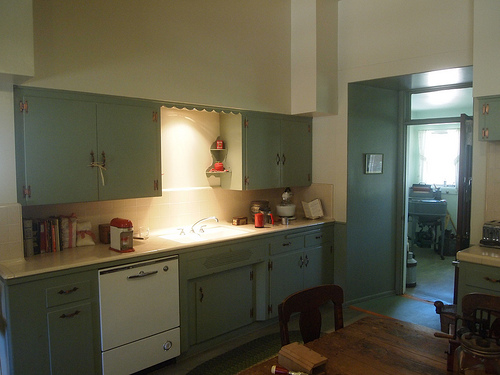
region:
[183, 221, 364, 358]
GREEN CABINETS IN KITCHEN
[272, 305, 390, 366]
WOOD FLOOR OF KITCHEN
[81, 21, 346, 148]
WHITE WALL IN KITCHEN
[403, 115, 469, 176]
WINDOW IN OTHER ROOM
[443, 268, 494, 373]
SMALL CHAIRS IN KITCHEN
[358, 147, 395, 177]
WHITE PHOTO ON WALL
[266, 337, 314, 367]
SMALL BOOOK ON TABLE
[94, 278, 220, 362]
WHITE DISHWASHER IN KITCHEN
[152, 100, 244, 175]
LIGHT OVER SINK IN KITCHEN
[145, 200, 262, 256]
WHITE KITCHEN SINK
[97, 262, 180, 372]
The white dishwasher.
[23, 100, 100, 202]
A green kitchen cabnet.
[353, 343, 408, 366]
Part of the wood table.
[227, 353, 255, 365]
Part of the blue rug.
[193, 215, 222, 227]
The silver water faucet.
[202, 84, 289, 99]
Part of the white wall.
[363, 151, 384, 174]
A picture on the wall.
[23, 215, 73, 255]
Books on the counter.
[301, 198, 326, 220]
An open book on the counter.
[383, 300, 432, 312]
Part of the floor.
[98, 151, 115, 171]
handle on cabinet door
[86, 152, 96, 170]
handle on cabinet door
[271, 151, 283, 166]
handle on cabinet door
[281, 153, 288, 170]
handle on cabinet door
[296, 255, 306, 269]
handle on cabinet door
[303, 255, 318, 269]
handle on cabinet door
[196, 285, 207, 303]
handle on cabinet door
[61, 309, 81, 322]
handle on cabinet door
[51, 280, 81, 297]
handle on cabinet door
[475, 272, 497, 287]
handle on cabinet door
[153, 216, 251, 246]
this is a sink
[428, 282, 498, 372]
this is a chair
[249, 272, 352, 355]
this is a chair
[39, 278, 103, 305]
a kitchen drawer cabinet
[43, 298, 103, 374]
a kitchen drawer cabinet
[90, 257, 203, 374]
a kitchen drawer cabinet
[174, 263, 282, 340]
a kitchen drawer cabinet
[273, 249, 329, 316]
a kitchen drawer cabinet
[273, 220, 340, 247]
a kitchen drawer cabinet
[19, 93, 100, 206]
a kitchen drawer cabinet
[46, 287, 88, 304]
A cabinet below the counter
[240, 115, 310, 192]
A cabinet above the counter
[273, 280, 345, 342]
A chair by the table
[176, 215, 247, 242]
A sink on the counter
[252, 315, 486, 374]
A table in the kitchen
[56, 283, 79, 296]
A handle on the drawer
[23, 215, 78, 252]
Books on the counter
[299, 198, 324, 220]
The book is open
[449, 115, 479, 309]
A door leading to another room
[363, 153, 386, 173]
A picture frame on the wall